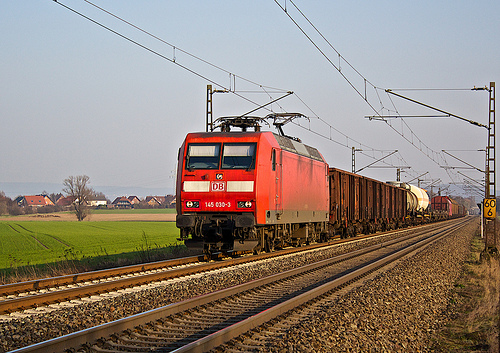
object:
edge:
[268, 290, 310, 313]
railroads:
[310, 230, 429, 265]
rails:
[0, 253, 198, 296]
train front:
[178, 130, 257, 212]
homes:
[13, 194, 59, 214]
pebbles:
[374, 284, 387, 295]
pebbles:
[427, 249, 442, 260]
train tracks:
[0, 254, 236, 314]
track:
[126, 254, 193, 286]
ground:
[371, 157, 420, 222]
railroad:
[141, 258, 328, 328]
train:
[174, 117, 467, 262]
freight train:
[168, 115, 408, 261]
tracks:
[3, 230, 431, 352]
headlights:
[183, 199, 200, 208]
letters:
[212, 182, 218, 190]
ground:
[0, 207, 499, 351]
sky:
[2, 1, 499, 204]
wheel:
[263, 231, 277, 254]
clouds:
[73, 145, 129, 157]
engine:
[173, 113, 330, 255]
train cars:
[327, 167, 407, 237]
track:
[9, 213, 70, 248]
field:
[12, 219, 160, 254]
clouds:
[42, 41, 142, 99]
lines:
[142, 46, 217, 85]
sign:
[468, 226, 481, 248]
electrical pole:
[480, 78, 495, 235]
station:
[406, 75, 484, 317]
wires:
[69, 8, 174, 64]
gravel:
[286, 329, 328, 353]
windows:
[184, 141, 222, 172]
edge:
[205, 233, 439, 351]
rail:
[4, 216, 475, 351]